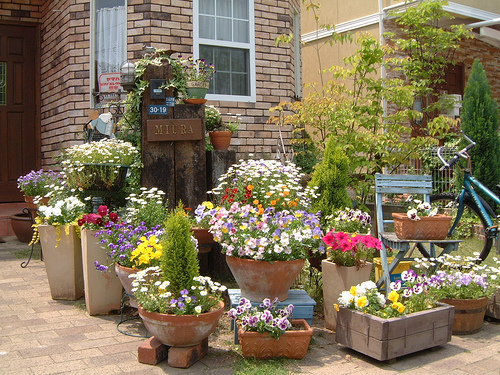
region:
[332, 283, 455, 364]
a box of flowers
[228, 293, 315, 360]
a planter with flowers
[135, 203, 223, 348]
a terra cotta planter with flowers and bush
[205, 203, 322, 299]
terra cotta pot with flowers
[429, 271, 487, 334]
half wooden barrel with flowers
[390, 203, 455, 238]
terra cotta planter with flowers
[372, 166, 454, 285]
a folding blue chair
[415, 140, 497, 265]
a blue bicycle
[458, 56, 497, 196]
a tall green bush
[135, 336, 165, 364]
a red brick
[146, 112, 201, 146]
MIURA is on a wooden sign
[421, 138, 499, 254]
bicycle is standing next to the chair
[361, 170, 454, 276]
blue foldable chair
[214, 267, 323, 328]
stepping stool is blue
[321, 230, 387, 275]
bright pink flowers in a tall planter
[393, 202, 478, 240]
white and purple flowers in a long planter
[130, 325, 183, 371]
planter sitting on two bricks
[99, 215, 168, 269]
purple and yellow flowers in a round planter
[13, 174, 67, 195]
light purple flowers in a planter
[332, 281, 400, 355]
white and yellow flowers in a planter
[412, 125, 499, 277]
Blue bike next to blue chair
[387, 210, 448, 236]
Terra cotta pot on blue chair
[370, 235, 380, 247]
Pink flower next to blue chair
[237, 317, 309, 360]
Terra cotta pot on ground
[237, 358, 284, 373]
Patch of green grass in front of terra cotta pot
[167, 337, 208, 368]
Brick underneath terra cotta pot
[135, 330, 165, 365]
Brick underneath terra cotta pot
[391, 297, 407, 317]
Yellow flower on planter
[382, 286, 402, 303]
Yellow flower near white and purple flower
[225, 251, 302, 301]
Large terra cotta pot on top of blue wooden stool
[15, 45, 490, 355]
pots of flowers in front of house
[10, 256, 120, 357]
tan and brown bricks covering sidewalk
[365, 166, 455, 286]
pale blue folding chair holding pansies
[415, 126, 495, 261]
blue bicycle behind chair and flowers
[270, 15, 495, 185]
bushes separating different homes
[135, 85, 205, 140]
house number and family name on signs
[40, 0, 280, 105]
windows on different angles of house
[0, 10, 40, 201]
wood entry door with glass panel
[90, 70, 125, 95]
red and white sign in window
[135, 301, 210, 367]
planter elevated with bricks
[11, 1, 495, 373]
plants are in pots in front of a house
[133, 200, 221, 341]
a round terracotta pot has an evergreen bush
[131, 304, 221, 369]
the pot is on bricks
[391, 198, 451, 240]
pansies are in a pot on a chair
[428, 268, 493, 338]
pansies are blooming in a barrel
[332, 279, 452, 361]
flowers are blooming in a wooden container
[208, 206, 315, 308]
pansies are in a terracotta pot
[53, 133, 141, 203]
white flowers are draping over a pot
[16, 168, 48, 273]
flowers are in a wrought iron stand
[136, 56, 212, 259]
flowers are on a wooden display